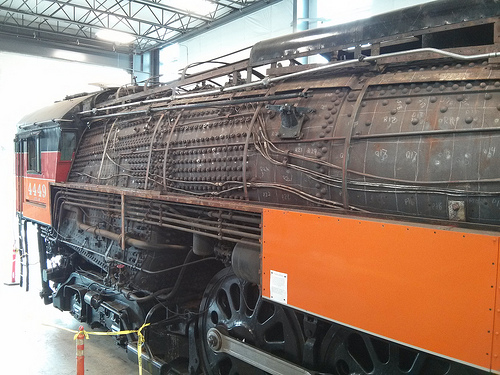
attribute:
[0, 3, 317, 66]
scaffolding — metal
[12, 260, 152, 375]
tape — yellow, caution tape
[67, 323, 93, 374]
cone — orange, white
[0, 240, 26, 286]
cone — white, orange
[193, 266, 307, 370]
wheel — large, black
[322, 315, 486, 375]
wheel — large, black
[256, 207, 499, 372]
panel — orange, painted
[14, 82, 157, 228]
front — black, red, orange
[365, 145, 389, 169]
measurement — handwritten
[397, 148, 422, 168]
measurement — handwritten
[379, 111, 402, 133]
measurement — handwritten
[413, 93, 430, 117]
measurement — handwritten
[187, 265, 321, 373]
train wheels — large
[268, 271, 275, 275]
screw — small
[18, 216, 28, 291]
ladder — metal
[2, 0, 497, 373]
train — iron, old, large, rusty, painted, red, orange, black, ancient, old fashioned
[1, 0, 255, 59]
support girders — black, metal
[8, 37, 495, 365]
train — roped off, old, displayed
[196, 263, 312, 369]
wheel — shiny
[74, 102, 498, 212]
line — steel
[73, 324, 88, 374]
post — orange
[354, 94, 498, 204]
writing — misc.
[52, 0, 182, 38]
beam — large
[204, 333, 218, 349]
screw — large